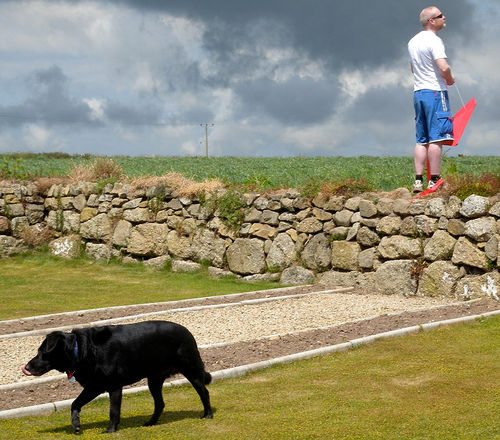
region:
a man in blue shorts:
[397, 1, 488, 218]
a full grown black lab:
[11, 314, 249, 436]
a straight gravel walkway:
[181, 275, 426, 341]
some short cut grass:
[173, 322, 498, 438]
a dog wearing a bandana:
[18, 305, 240, 425]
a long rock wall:
[7, 170, 499, 300]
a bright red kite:
[431, 80, 480, 215]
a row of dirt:
[32, 270, 307, 320]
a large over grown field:
[63, 105, 402, 226]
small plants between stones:
[32, 177, 81, 252]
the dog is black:
[3, 302, 238, 434]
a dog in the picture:
[17, 293, 231, 436]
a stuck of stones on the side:
[1, 179, 498, 304]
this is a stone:
[229, 235, 271, 275]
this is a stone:
[332, 240, 361, 272]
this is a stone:
[378, 262, 422, 301]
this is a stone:
[131, 221, 172, 259]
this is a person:
[404, 4, 471, 196]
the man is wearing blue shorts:
[406, 87, 464, 151]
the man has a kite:
[383, 0, 483, 223]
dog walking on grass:
[17, 316, 242, 434]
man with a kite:
[398, 5, 488, 202]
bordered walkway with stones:
[1, 280, 496, 382]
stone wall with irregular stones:
[4, 183, 499, 300]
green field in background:
[5, 154, 499, 196]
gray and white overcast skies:
[3, 0, 498, 147]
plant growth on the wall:
[31, 172, 315, 227]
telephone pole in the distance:
[188, 117, 228, 162]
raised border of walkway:
[218, 302, 498, 372]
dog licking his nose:
[12, 319, 72, 381]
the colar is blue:
[70, 322, 78, 374]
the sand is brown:
[282, 328, 342, 344]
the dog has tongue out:
[14, 343, 224, 412]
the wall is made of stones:
[237, 226, 422, 272]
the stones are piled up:
[204, 221, 387, 266]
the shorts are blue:
[402, 94, 454, 137]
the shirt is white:
[392, 35, 449, 87]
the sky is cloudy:
[227, 25, 370, 107]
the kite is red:
[455, 103, 477, 140]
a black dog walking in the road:
[26, 312, 224, 434]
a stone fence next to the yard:
[2, 193, 499, 301]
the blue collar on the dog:
[63, 337, 78, 377]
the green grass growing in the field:
[1, 146, 498, 189]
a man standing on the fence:
[405, 3, 465, 195]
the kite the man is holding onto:
[444, 90, 481, 151]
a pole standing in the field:
[197, 117, 219, 157]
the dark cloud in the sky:
[130, 1, 465, 113]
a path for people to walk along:
[0, 275, 496, 421]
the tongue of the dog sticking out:
[18, 364, 32, 376]